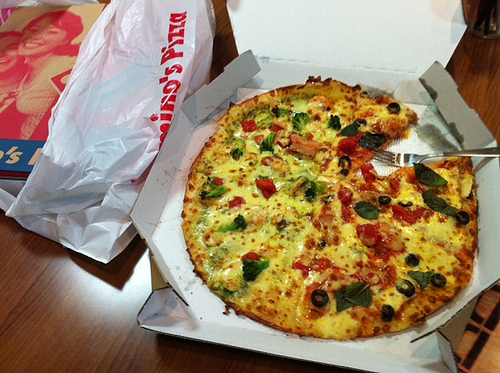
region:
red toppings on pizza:
[245, 175, 281, 206]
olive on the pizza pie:
[306, 289, 333, 311]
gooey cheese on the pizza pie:
[228, 215, 263, 247]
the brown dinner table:
[32, 304, 94, 349]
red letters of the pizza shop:
[148, 23, 188, 104]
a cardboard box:
[143, 302, 208, 335]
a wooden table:
[51, 313, 127, 358]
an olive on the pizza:
[309, 287, 333, 309]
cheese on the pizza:
[266, 213, 307, 258]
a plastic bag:
[66, 122, 127, 164]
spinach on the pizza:
[326, 286, 375, 305]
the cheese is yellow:
[221, 227, 246, 248]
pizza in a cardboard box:
[177, 73, 480, 340]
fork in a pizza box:
[367, 137, 499, 173]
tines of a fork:
[367, 143, 399, 165]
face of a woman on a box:
[16, 10, 83, 56]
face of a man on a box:
[0, 25, 25, 82]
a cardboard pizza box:
[123, 2, 495, 371]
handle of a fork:
[434, 144, 499, 160]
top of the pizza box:
[222, 0, 470, 78]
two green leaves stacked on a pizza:
[333, 275, 375, 317]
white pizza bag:
[8, 0, 226, 265]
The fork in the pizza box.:
[365, 134, 496, 182]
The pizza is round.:
[192, 80, 478, 333]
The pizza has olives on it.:
[309, 268, 395, 323]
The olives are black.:
[374, 190, 419, 212]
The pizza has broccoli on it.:
[241, 257, 271, 279]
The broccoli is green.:
[204, 175, 228, 203]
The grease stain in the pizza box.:
[416, 115, 459, 156]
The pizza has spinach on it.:
[335, 270, 375, 315]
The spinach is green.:
[415, 161, 460, 212]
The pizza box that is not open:
[0, 5, 109, 170]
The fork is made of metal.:
[375, 138, 498, 169]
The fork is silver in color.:
[371, 142, 498, 171]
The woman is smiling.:
[20, 9, 84, 56]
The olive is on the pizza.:
[306, 284, 330, 309]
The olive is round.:
[308, 284, 334, 314]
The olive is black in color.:
[308, 285, 333, 309]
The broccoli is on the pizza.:
[258, 132, 277, 157]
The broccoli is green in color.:
[241, 259, 269, 281]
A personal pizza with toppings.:
[181, 74, 486, 340]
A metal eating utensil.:
[352, 146, 498, 168]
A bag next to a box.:
[6, 0, 221, 266]